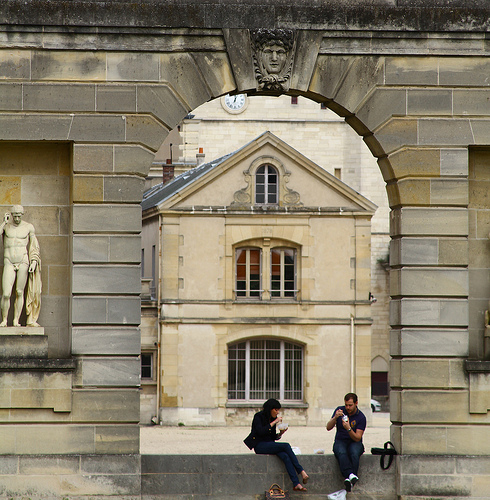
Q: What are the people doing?
A: Eating.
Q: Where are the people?
A: Under the arch.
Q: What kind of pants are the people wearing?
A: Jeans.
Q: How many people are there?
A: Two.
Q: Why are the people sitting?
A: So they can eat.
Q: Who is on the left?
A: The woman.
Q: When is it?
A: Day time.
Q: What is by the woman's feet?
A: Her purse.